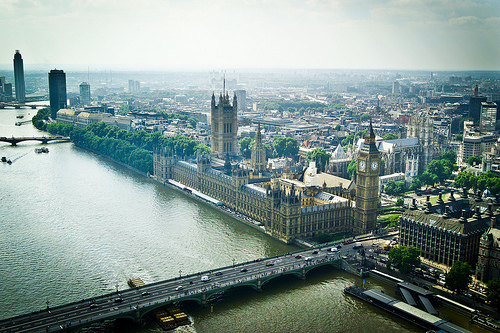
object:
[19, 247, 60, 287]
water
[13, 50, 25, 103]
building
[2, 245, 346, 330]
bridge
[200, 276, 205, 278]
vehicles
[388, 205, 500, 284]
buildings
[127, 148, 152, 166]
trees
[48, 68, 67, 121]
tower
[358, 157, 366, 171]
clock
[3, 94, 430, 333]
river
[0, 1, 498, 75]
sky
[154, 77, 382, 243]
castle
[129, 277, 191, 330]
boat